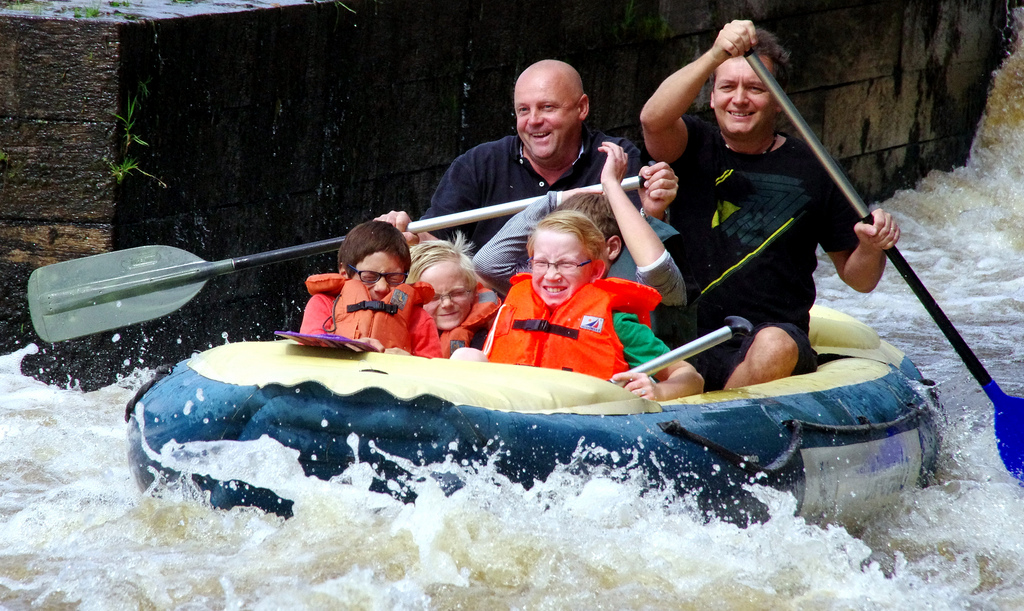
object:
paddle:
[733, 37, 1024, 494]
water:
[2, 37, 1023, 611]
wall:
[2, 0, 1007, 353]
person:
[367, 56, 677, 253]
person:
[636, 15, 901, 391]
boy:
[484, 209, 708, 404]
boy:
[406, 230, 501, 362]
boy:
[298, 220, 445, 358]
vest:
[485, 272, 663, 382]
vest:
[440, 282, 503, 360]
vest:
[306, 269, 437, 355]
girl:
[466, 140, 687, 342]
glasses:
[526, 257, 592, 274]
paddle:
[20, 176, 645, 347]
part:
[510, 57, 590, 170]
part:
[336, 221, 412, 305]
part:
[406, 237, 480, 332]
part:
[526, 209, 606, 310]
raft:
[121, 302, 943, 541]